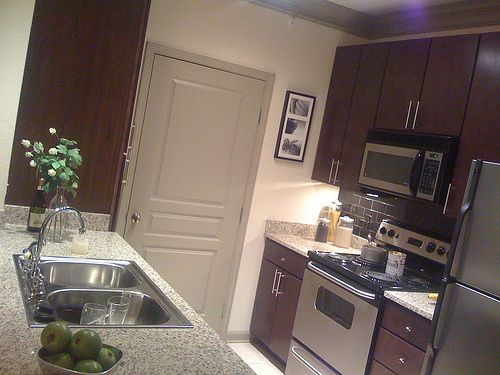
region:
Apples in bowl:
[31, 331, 91, 373]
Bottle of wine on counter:
[24, 171, 82, 245]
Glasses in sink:
[82, 288, 165, 330]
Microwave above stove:
[361, 138, 429, 213]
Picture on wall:
[282, 55, 302, 217]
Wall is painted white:
[256, 42, 313, 107]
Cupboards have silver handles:
[321, 137, 350, 195]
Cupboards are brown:
[335, 50, 449, 163]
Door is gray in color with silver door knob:
[132, 106, 235, 247]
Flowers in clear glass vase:
[21, 124, 109, 244]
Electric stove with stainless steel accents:
[295, 205, 462, 373]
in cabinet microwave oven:
[346, 124, 473, 200]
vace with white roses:
[17, 116, 99, 245]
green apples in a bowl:
[27, 314, 125, 374]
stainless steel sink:
[5, 199, 192, 333]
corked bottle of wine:
[15, 174, 63, 233]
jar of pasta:
[320, 193, 345, 244]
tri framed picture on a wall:
[264, 76, 324, 172]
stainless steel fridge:
[415, 148, 496, 374]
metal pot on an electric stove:
[355, 228, 390, 263]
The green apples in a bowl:
[39, 319, 126, 370]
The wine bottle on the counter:
[27, 176, 51, 233]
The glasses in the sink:
[82, 289, 149, 336]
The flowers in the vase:
[17, 124, 80, 241]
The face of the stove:
[292, 258, 380, 369]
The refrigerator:
[416, 152, 498, 374]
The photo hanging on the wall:
[272, 87, 317, 168]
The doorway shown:
[119, 40, 279, 362]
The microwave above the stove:
[357, 137, 447, 210]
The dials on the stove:
[376, 222, 450, 257]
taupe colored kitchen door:
[156, 61, 243, 261]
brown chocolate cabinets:
[262, 235, 305, 362]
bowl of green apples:
[39, 321, 126, 373]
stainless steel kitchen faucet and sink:
[21, 213, 171, 338]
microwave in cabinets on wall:
[364, 130, 459, 211]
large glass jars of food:
[300, 189, 366, 244]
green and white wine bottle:
[25, 167, 60, 231]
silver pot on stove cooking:
[351, 235, 394, 265]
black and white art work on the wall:
[278, 56, 316, 178]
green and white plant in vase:
[29, 127, 106, 209]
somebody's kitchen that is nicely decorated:
[1, 2, 499, 372]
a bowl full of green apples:
[36, 322, 117, 374]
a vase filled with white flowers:
[16, 120, 90, 255]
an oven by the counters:
[276, 200, 445, 372]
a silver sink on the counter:
[12, 248, 197, 329]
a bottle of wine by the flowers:
[16, 178, 52, 231]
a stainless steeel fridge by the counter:
[414, 153, 498, 373]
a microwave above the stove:
[352, 124, 450, 209]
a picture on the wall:
[281, 75, 314, 169]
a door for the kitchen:
[122, 42, 261, 345]